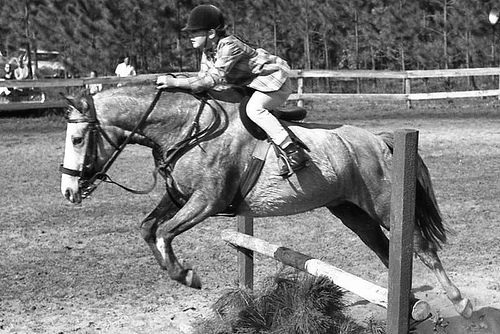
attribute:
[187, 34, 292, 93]
jacket — checkered